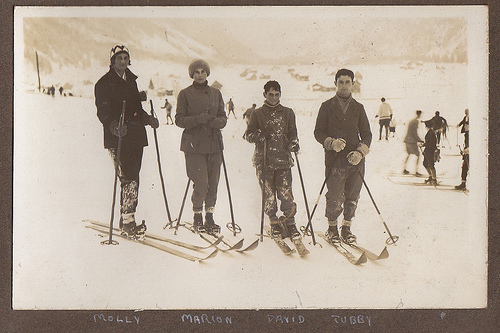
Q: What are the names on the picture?
A: Molly, Marlon, David, Tubby.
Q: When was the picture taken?
A: During the daytime.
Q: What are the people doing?
A: Skiing.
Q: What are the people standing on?
A: Snow.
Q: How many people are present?
A: Fourteen.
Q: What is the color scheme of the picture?
A: Black and white.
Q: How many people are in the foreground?
A: Four.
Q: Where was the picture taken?
A: On a ski slope.